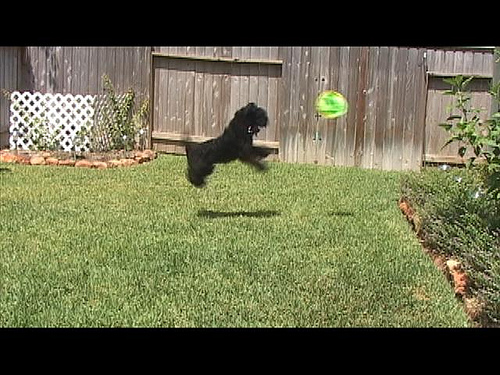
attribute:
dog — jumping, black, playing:
[181, 103, 271, 187]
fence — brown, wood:
[0, 45, 498, 174]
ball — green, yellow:
[314, 88, 348, 121]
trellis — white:
[9, 91, 132, 153]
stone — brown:
[144, 148, 158, 158]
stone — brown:
[119, 159, 140, 165]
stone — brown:
[73, 159, 106, 169]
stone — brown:
[41, 155, 60, 164]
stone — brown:
[0, 147, 17, 164]